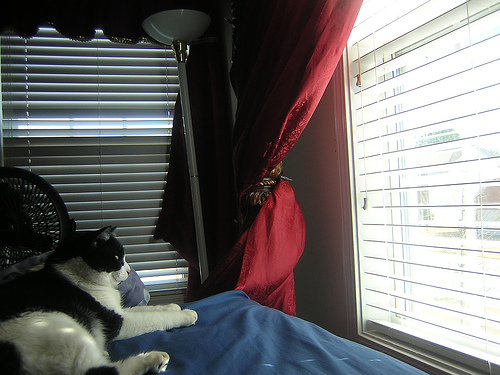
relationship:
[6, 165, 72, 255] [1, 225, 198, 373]
fan behind cat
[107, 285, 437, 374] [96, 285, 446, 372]
sheets on bed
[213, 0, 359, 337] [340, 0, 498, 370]
red drapes on window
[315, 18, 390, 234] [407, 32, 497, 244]
cord on blinds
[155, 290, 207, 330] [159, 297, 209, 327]
paw of cat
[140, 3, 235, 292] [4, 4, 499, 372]
lamp in room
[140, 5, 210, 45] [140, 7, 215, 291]
lamp shade on lamp